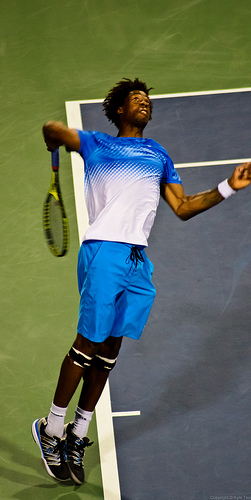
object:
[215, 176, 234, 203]
sweatband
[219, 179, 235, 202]
wrist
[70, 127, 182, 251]
shirt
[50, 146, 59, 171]
handle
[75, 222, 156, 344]
shorts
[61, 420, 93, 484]
shoe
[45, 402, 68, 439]
white sock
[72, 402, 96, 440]
white sock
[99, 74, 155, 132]
hair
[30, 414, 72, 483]
tennis shoes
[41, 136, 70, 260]
racket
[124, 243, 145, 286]
string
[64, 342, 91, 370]
knee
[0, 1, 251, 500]
court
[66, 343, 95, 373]
knee pads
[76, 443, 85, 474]
lace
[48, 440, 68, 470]
lace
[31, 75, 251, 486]
tennis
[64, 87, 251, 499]
play area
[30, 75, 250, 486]
he